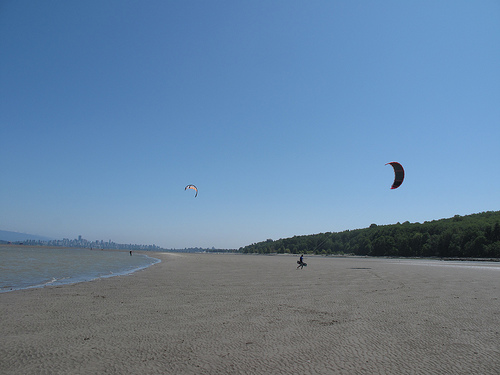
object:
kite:
[383, 162, 404, 190]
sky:
[0, 28, 500, 94]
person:
[296, 254, 304, 269]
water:
[41, 247, 81, 283]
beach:
[164, 273, 248, 347]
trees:
[365, 235, 401, 257]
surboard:
[300, 262, 307, 269]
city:
[8, 235, 169, 252]